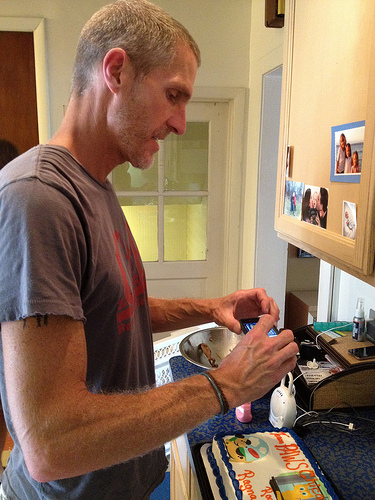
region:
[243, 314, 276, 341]
phone in the man's hand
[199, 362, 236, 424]
bracelet on man's wrist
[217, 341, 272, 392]
veins in the man's hand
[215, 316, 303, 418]
the man's right hand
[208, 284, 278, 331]
the man's left hand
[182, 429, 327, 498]
cake on the counter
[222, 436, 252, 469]
dog on the cake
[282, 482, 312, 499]
yellow cat on the cake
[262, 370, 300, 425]
white timer on counter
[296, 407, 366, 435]
wires on the counter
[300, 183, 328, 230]
a picture of two people kissing a third in between them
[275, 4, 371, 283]
light brown wooden cabinet with pictures on it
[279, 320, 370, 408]
light brown and dark brown trimmed storage box with lots of things in it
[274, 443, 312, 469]
the word "PAWS' in orange on a white frosted cake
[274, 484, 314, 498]
partial decorative picture of a yellow cat with blue eyes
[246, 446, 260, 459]
red frisbee decoration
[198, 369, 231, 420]
black wrist band on a right wrist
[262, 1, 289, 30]
unknown brown and yellowish box mounted close to the ceiling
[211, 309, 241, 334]
man's left thumb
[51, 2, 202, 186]
head of a man with short blonde hair and stubbly beard looking down in concentration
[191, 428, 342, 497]
cake with white frosting, blue trim and a colorful decoration on it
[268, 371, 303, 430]
white object that looks like a baby monitor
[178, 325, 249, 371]
metal wok with utensil in it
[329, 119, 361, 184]
picture of three females standing in front of a body of water framed in blue construction paper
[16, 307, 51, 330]
partial tattoo peeking out from underneath a purle shirtsleeve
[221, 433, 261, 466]
decoration on a cake of a puppy catching a frisbee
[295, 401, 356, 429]
white electrical cord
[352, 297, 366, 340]
undistinguishable bottle with white spray lid and clear cap on it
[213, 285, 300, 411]
man's hands taking a picture with a phone camera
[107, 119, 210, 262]
four paned window in a white door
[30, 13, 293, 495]
this is a man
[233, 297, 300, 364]
this is a cell phone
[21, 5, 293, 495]
a man holding a cell phone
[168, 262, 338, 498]
this is taking a picture of the cake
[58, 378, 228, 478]
blonde hair arm on man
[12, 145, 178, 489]
man wearing grey shirt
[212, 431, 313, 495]
white icing on cake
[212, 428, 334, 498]
blue trim icing on cake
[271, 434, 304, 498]
orange writing on cake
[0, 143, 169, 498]
the shirt is gray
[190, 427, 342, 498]
the cake is on the tray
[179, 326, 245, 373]
the bowl is silver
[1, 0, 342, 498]
the man is taking a picture of the cake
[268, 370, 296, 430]
the baby monitor is white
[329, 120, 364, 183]
photo on the cupboard door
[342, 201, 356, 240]
photo on the cupboard door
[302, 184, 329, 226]
photo on the cupboard door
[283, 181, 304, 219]
photo on the cupboard door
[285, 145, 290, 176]
photo on the cupboard door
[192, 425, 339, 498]
cake on a black tray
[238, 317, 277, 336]
black smart phone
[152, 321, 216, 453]
white plastic baby gate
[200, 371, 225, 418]
blue rubber arm band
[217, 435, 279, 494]
a cake o nthe counter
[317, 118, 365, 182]
a picture on the cabinet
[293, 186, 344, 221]
a picture on the cabinet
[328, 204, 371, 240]
a picture on the cabinet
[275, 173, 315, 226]
a picture on the cabinet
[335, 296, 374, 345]
a bottle on the counter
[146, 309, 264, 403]
a silver bowl on the counter